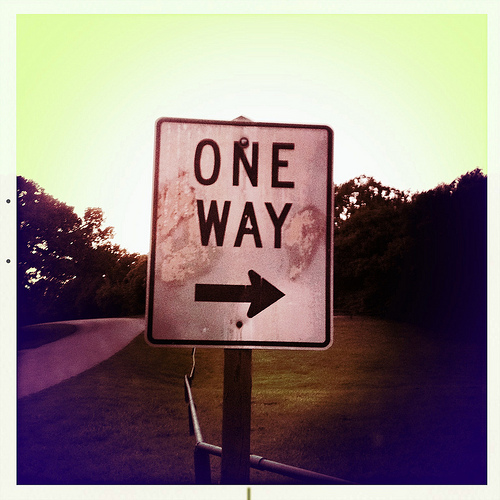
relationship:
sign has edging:
[142, 113, 337, 353] [140, 113, 338, 355]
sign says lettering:
[142, 113, 337, 353] [193, 138, 295, 248]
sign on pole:
[142, 113, 337, 353] [217, 348, 255, 483]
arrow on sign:
[192, 268, 287, 319] [142, 113, 337, 353]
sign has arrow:
[142, 113, 337, 353] [192, 268, 287, 319]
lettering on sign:
[192, 135, 299, 256] [142, 113, 337, 353]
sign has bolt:
[142, 113, 337, 353] [233, 319, 247, 330]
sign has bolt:
[142, 113, 337, 353] [239, 135, 252, 150]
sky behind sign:
[17, 15, 491, 289] [142, 113, 337, 353]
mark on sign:
[159, 168, 220, 292] [142, 113, 337, 353]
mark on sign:
[280, 202, 325, 282] [142, 113, 337, 353]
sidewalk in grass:
[20, 313, 152, 399] [23, 316, 487, 487]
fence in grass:
[183, 346, 357, 484] [23, 316, 487, 487]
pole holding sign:
[217, 348, 255, 483] [142, 113, 337, 353]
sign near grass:
[142, 113, 337, 353] [23, 316, 487, 487]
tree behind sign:
[95, 283, 137, 317] [142, 113, 337, 353]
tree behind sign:
[18, 172, 89, 323] [142, 113, 337, 353]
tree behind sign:
[336, 198, 402, 320] [142, 113, 337, 353]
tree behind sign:
[336, 169, 410, 237] [142, 113, 337, 353]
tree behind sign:
[404, 165, 486, 329] [142, 113, 337, 353]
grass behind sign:
[23, 316, 487, 487] [142, 113, 337, 353]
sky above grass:
[17, 15, 491, 289] [23, 316, 487, 487]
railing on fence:
[182, 371, 208, 449] [183, 346, 357, 484]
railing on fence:
[202, 441, 343, 484] [183, 346, 357, 484]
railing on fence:
[186, 346, 198, 382] [183, 346, 357, 484]